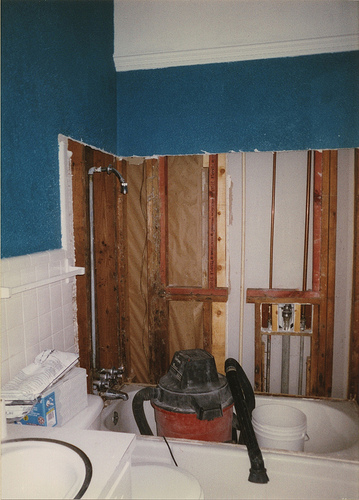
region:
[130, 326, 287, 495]
vacuum cleaner in bathtub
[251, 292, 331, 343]
electrical box in wall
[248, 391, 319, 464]
bucket in bathtub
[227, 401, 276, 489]
nozzle on vacuum cleaner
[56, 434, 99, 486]
black trim on edge of sink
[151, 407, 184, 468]
power cord of vacuum cleaner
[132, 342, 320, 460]
vacuum cleaner and bucket in bathtub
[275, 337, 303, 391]
electrical conduit behind wall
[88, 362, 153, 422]
faucet in bathtub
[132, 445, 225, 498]
seat of toilet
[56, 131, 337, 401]
exposed wall construction beams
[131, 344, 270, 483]
red and black industrial vacuum cleaner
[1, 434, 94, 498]
oval shaped bathroom sink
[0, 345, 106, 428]
assorted packages on toilet tank lid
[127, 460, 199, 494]
toilet seat lid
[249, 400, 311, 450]
white industrial bucket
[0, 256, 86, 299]
empty towel bar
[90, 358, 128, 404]
group of metal bathtub plumbing fixtures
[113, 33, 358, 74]
wooden molding painted white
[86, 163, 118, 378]
shower head and pipe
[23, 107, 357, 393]
exposed unfinished bathroom wall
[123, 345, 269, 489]
one large wet dry vacuum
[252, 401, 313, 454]
one plastic white bucket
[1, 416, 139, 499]
one white bathroom sink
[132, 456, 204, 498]
top of white toilet lid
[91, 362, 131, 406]
shiny metal bathtub faucet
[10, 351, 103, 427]
items on top of white toilet tank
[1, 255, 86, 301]
white ceramic towel bar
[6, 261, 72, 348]
white square bathroom tiles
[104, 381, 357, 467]
items inside white bathtub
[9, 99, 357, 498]
a bathroom is in the throws of remodeling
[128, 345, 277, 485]
a shop vacuum is in a bathtub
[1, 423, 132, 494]
the sink is round in the remodel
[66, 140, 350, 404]
a shower wall has been gutted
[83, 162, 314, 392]
the piping has remained in the bathroom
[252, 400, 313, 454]
a handled white bucket is in the tub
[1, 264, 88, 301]
a towel rack is on the wall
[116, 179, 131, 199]
a shower head is on the pipe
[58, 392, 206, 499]
a toilet is white in the room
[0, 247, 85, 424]
white ceramic tile is on the wall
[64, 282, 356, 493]
a bathroom tub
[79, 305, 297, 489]
a white bathroom tub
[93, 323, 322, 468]
a shopvac in a tub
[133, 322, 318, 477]
a shopvac in a bathroom tub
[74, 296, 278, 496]
a shopvac in a bathtub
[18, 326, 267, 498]
a white bathroom toilet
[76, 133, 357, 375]
a bathtub wall gutted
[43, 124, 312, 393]
a bathroom wall gutted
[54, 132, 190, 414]
a silver bathroom shower head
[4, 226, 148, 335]
a white railing on the wall